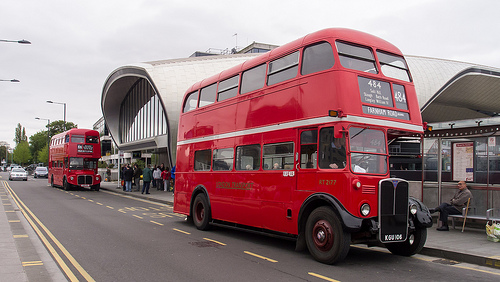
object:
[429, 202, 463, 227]
pants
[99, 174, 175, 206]
curb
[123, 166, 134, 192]
man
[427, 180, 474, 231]
man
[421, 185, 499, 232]
bench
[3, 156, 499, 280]
road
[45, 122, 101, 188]
bus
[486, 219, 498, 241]
bag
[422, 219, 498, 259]
platform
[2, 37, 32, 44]
street lamp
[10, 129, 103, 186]
traffic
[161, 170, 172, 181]
red jacket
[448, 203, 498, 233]
chair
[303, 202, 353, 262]
tire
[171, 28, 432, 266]
bus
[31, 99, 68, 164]
light poles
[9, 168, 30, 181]
car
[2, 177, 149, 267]
road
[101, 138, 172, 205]
platform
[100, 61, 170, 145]
shade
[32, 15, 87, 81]
thick clouds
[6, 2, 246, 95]
sky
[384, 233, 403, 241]
license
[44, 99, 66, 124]
street lamp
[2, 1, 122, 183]
background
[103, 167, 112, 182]
person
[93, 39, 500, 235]
building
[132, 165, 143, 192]
person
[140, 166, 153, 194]
man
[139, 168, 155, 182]
jacket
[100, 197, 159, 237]
yellow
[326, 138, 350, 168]
driver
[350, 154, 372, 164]
steering wheel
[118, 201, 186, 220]
lettering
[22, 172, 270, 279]
street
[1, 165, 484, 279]
street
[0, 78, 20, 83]
light pole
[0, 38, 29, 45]
light pole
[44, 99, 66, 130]
light pole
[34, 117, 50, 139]
light pole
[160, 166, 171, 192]
man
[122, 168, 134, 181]
jacket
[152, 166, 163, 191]
person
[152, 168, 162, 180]
jacket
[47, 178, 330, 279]
markings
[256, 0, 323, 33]
clouds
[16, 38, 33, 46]
lamp